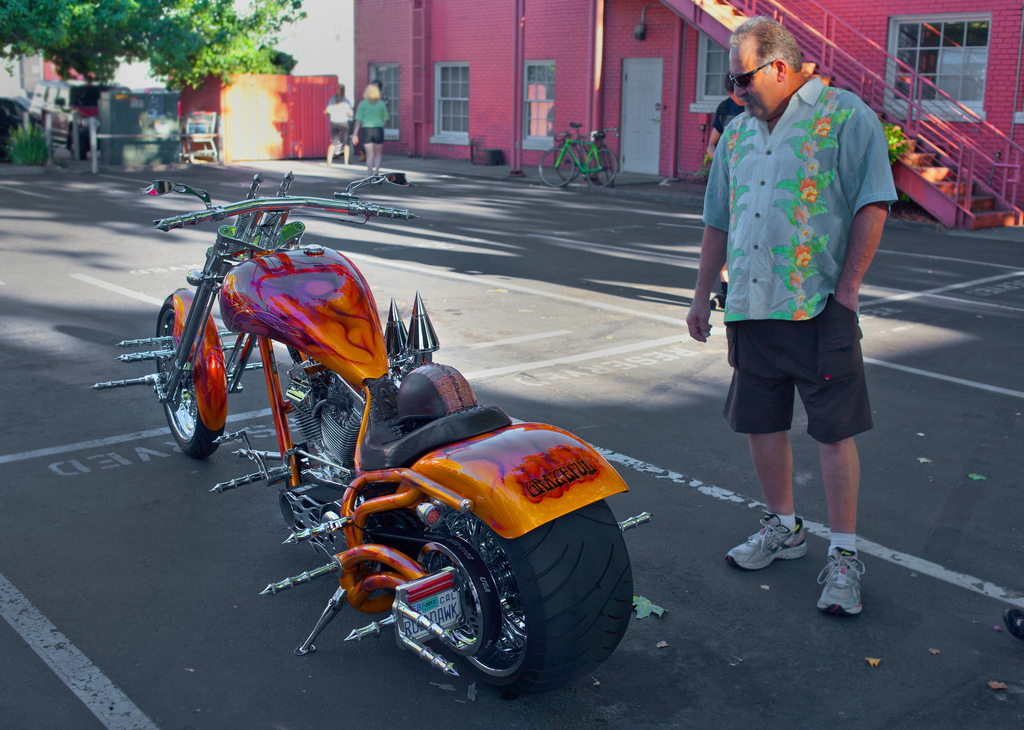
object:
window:
[433, 60, 468, 137]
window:
[367, 61, 399, 134]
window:
[882, 11, 992, 121]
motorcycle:
[90, 171, 652, 695]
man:
[685, 16, 898, 615]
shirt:
[703, 77, 898, 325]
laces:
[748, 519, 780, 553]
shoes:
[725, 509, 865, 615]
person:
[351, 84, 389, 185]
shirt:
[354, 98, 389, 127]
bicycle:
[539, 122, 619, 189]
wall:
[354, 3, 1024, 215]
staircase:
[663, 0, 1024, 230]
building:
[354, 0, 1024, 230]